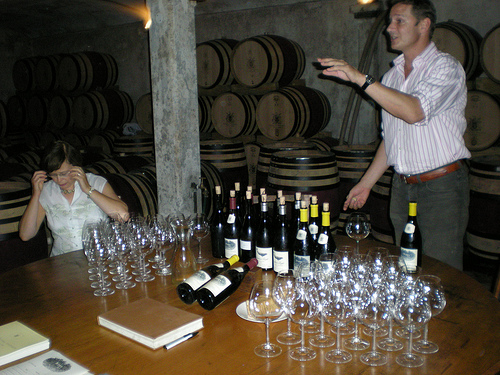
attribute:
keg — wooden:
[227, 32, 307, 90]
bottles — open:
[208, 180, 332, 277]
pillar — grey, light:
[144, 0, 202, 222]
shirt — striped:
[349, 32, 494, 187]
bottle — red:
[195, 246, 247, 311]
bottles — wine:
[192, 181, 322, 274]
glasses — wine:
[78, 208, 213, 295]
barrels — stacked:
[202, 34, 362, 231]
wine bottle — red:
[274, 193, 293, 276]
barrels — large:
[16, 24, 496, 243]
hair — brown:
[31, 139, 91, 178]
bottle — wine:
[294, 188, 346, 273]